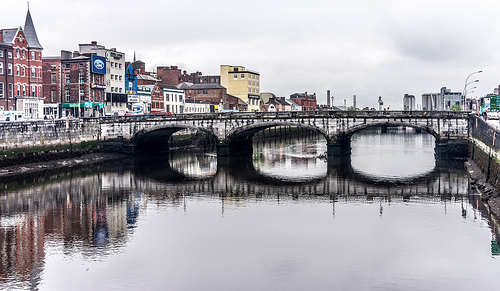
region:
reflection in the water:
[75, 200, 132, 270]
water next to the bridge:
[180, 175, 235, 225]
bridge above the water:
[255, 95, 335, 140]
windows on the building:
[5, 50, 30, 80]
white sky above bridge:
[315, 20, 375, 67]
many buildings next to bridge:
[85, 50, 206, 112]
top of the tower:
[20, 5, 45, 30]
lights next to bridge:
[460, 60, 488, 96]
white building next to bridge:
[108, 45, 128, 91]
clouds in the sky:
[185, 18, 355, 52]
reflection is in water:
[83, 161, 439, 242]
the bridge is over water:
[183, 97, 461, 187]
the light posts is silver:
[459, 68, 494, 121]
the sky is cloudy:
[276, 10, 443, 76]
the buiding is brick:
[2, 8, 53, 103]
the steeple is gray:
[10, 7, 53, 52]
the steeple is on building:
[4, 10, 39, 96]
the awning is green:
[64, 96, 111, 108]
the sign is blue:
[88, 53, 110, 74]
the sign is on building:
[62, 50, 112, 119]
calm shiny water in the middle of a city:
[0, 128, 499, 289]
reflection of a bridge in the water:
[106, 162, 469, 195]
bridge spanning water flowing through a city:
[101, 111, 471, 173]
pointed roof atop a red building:
[22, 1, 43, 49]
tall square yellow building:
[219, 63, 259, 113]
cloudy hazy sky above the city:
[0, 0, 497, 107]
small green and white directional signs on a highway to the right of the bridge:
[477, 95, 499, 113]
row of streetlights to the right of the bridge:
[462, 68, 482, 108]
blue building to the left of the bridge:
[122, 60, 138, 114]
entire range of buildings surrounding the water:
[0, 0, 462, 117]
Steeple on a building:
[6, 0, 53, 54]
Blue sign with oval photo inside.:
[87, 49, 109, 76]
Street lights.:
[459, 66, 482, 108]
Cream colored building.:
[215, 60, 269, 111]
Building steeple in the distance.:
[130, 42, 137, 64]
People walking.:
[43, 111, 63, 120]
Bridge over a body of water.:
[94, 101, 474, 171]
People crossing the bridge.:
[377, 106, 395, 120]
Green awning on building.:
[59, 96, 109, 111]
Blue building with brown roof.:
[121, 60, 141, 97]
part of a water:
[270, 175, 323, 241]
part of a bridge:
[306, 91, 345, 136]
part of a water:
[244, 195, 289, 252]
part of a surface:
[215, 163, 292, 251]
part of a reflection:
[273, 167, 298, 187]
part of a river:
[134, 147, 198, 223]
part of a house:
[280, 70, 314, 102]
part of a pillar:
[310, 100, 342, 155]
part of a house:
[81, 36, 111, 74]